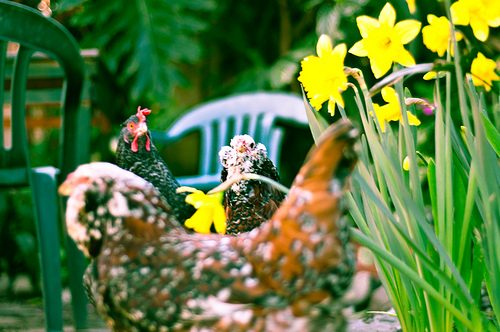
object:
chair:
[154, 90, 331, 193]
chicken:
[108, 100, 194, 227]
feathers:
[153, 160, 166, 185]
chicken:
[56, 97, 436, 332]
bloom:
[295, 32, 349, 116]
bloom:
[465, 50, 499, 93]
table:
[1, 163, 61, 172]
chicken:
[214, 133, 289, 233]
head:
[119, 106, 152, 139]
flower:
[421, 13, 464, 58]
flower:
[367, 86, 422, 134]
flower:
[174, 185, 227, 237]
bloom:
[447, 0, 499, 44]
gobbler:
[217, 134, 287, 238]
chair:
[0, 0, 101, 331]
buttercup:
[347, 2, 423, 80]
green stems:
[365, 128, 473, 331]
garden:
[1, 1, 500, 332]